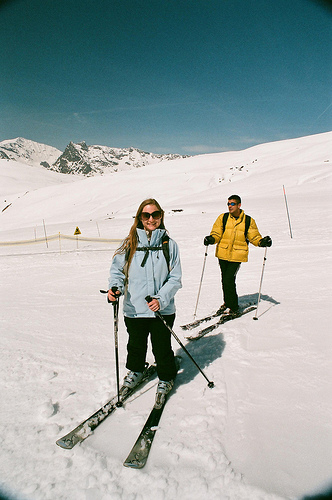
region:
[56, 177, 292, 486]
Two people on skis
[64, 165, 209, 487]
A girl in a blue jacket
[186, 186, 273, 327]
A boy in a yellow jacket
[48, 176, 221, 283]
She is wearing sunglasses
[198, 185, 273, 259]
He is wearing sunglasses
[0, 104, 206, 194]
Mountains in the distance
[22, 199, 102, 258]
A yellow sign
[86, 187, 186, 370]
She has very long hair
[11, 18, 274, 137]
The sky is clear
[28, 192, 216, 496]
Her skis are black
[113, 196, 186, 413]
woman wearing skiis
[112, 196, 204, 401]
woman wearing blue jacket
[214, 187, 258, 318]
man wearing yellow jacket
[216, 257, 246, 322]
man wearing black long pants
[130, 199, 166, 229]
woman wearing round sunglasses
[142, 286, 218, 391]
LONG BLACK SKII STICK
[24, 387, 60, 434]
CHUNKS OF WHITE SNOW ON GROUND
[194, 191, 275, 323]
MAN WEARING BLUE SUNGLASSES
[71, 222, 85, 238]
TRIANGULAR YELLOW SIGN ON POLE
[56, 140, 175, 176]
WHITE SNOW ON MOUNTAINTOP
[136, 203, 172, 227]
girl is smiling at camera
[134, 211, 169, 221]
girl wearing goggles on her face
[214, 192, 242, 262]
man with yellow jacket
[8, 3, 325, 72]
no clouds in the sky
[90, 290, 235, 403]
girl holding two ski poles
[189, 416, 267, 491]
snow on ground is white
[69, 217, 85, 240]
caution sign in background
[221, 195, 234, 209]
man looking in a different direction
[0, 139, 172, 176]
snow on the mountain tops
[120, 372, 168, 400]
the girls boots are gray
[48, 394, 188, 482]
a pair of black skis in the snow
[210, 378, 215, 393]
the round tip of a ski pole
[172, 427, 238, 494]
an area of disturbed white snow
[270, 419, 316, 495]
an area of smooth white snow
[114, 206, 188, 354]
a woman in a blue coat on skis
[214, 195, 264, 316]
a man in a yellow coat on skis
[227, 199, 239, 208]
a pair of black sunglasses on a man's face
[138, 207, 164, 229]
a pair of black sunglasses on a woman's face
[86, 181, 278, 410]
two people on skis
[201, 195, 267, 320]
man wearing puffy yellow jacket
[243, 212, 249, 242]
black backpack straps visible on his sholuders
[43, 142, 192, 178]
rocky mountain top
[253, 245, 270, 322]
man holding metal silver ski pole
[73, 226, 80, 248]
triangular yellow sign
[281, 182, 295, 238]
slalom poles in the snow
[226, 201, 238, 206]
man is wearing sunglasses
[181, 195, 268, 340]
man is skiing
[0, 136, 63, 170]
mountain next to rocky gray mountain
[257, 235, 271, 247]
man wearing black gloves